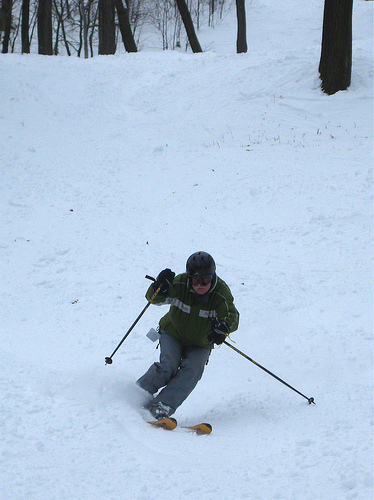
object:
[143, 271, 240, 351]
jacket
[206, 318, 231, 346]
glove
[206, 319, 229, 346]
hand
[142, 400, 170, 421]
shoe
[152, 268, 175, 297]
black gloves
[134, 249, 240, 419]
skier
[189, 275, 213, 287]
goggles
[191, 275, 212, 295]
face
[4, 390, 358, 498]
snow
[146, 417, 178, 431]
board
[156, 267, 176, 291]
hand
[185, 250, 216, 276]
helmet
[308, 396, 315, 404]
hooker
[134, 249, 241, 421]
person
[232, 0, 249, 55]
trees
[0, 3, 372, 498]
hill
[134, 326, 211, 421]
pants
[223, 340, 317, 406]
pole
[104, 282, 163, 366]
pole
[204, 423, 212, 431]
tip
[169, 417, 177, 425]
tip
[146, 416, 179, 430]
ski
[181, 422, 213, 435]
ski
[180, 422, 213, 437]
board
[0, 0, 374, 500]
ground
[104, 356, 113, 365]
hooker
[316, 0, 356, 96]
trees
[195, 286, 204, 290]
beard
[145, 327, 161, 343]
tag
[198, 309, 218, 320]
stripe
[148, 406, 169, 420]
part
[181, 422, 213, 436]
part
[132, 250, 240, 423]
man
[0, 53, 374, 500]
snow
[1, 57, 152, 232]
slope